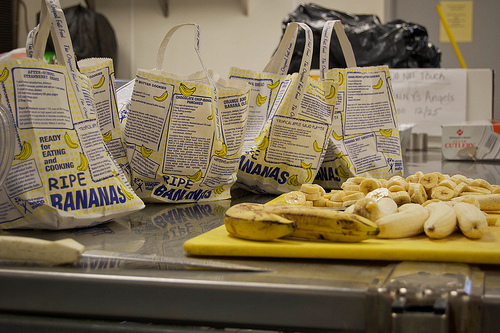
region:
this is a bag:
[135, 70, 242, 188]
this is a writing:
[35, 188, 132, 213]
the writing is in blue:
[33, 185, 130, 208]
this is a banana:
[211, 188, 286, 245]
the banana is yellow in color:
[224, 205, 256, 235]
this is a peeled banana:
[423, 195, 463, 250]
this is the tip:
[286, 219, 306, 229]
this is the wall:
[199, 28, 255, 42]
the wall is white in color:
[214, 10, 261, 50]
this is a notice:
[441, 2, 482, 32]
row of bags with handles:
[1, 0, 403, 228]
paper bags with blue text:
[1, 56, 403, 226]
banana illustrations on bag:
[15, 132, 87, 174]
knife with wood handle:
[0, 234, 270, 278]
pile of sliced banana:
[285, 172, 497, 208]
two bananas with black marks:
[224, 201, 380, 242]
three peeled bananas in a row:
[375, 203, 486, 240]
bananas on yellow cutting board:
[185, 173, 499, 262]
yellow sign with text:
[440, 1, 472, 43]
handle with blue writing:
[318, 19, 356, 68]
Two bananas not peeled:
[220, 198, 381, 241]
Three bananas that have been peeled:
[375, 197, 489, 241]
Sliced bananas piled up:
[286, 167, 498, 209]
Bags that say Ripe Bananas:
[0, 1, 407, 228]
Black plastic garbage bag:
[273, 1, 443, 68]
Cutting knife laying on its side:
[0, 233, 274, 277]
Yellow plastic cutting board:
[184, 183, 499, 267]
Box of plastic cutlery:
[437, 120, 498, 159]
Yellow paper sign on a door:
[435, 0, 476, 44]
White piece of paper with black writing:
[382, 68, 467, 136]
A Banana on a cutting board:
[222, 197, 295, 247]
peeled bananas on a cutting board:
[390, 196, 491, 234]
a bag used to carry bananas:
[114, 68, 257, 215]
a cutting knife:
[12, 228, 292, 290]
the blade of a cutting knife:
[83, 239, 275, 290]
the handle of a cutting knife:
[3, 226, 97, 276]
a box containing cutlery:
[432, 112, 497, 164]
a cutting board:
[185, 229, 497, 269]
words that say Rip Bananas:
[42, 173, 127, 215]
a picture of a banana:
[59, 130, 79, 152]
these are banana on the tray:
[263, 165, 490, 238]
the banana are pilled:
[405, 198, 487, 239]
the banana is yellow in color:
[319, 205, 366, 237]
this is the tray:
[350, 241, 375, 258]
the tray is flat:
[337, 238, 385, 265]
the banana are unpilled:
[236, 203, 353, 234]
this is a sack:
[11, 66, 103, 205]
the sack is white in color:
[12, 68, 99, 200]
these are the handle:
[281, 16, 355, 71]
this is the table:
[137, 208, 171, 262]